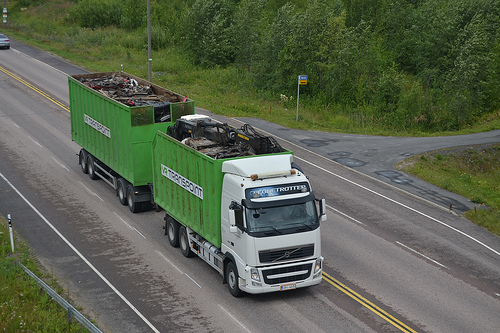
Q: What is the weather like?
A: Cloudy.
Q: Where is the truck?
A: On the road.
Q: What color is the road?
A: Gray.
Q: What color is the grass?
A: Green.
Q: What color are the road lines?
A: Yellow.